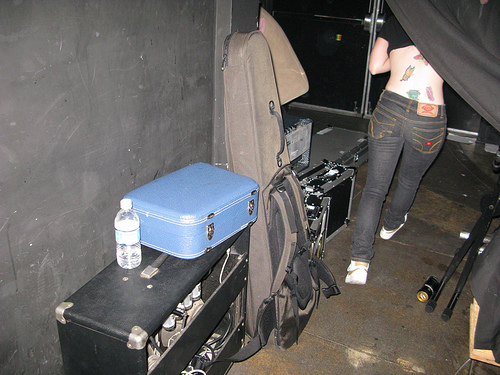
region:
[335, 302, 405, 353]
The ground is made of concrete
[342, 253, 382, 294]
The shoe of the person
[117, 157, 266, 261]
The suitcase on the stand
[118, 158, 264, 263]
The suitcase is the color blue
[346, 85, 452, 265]
The woman is wearing pants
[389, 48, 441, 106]
The woman has tattoos on her back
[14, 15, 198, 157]
The wall is the color grey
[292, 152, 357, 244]
The trunk is the color black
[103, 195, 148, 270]
The water bottle on the stand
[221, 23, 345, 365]
The guitar case is the color gray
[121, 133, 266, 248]
the suitcase is blue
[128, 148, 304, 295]
the suitcase is blue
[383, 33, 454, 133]
tattoos on the back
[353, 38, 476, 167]
tattoos on the back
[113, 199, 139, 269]
A plastic bottle of water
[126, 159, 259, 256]
A suitcase by the water bottle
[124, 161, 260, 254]
The suitcase is blue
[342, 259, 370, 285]
A white shoe on the left foot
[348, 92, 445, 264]
The woman is wearing pants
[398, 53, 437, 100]
The woman has tattoos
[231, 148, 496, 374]
The ground below the suitcase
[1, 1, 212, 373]
The wall behind the water bottle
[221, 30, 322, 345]
A large brown case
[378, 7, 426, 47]
The woman is wearing a black shirt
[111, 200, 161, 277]
BOTTLE OF WATER IS ON AMP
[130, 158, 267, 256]
SUIT CASE IS BLUE IN COLOR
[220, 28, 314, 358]
GUITAR CASE IS LEANING AGAINST WALL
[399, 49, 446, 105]
PERSON HAS TATTOOS ON BACK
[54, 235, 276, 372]
AMP IS BLACK IN COLOR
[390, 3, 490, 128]
BLACK CURTAIN IS PARTIALLY OPEN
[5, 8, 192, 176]
WALL IS BLACK IN COLOR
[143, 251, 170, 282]
HANDLE ON AMP IS BLACK AND SILVER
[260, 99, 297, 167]
HANDLE ON GUITAR CASE IS BLACK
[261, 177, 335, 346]
GUITAR CASE HAS SHOULDER STRAPS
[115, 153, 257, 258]
Blue luggage on the black case.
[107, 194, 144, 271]
Bottle of water on the black case.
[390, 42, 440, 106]
Tattoos on the back.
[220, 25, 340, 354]
Music case on the wall.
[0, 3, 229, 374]
Gray wall beside the black case.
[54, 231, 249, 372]
Black case on the floor.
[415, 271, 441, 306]
Can on the floor.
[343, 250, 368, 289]
White shoe on the foot.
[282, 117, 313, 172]
White plastic container.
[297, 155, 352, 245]
Silver and black case on the floor.